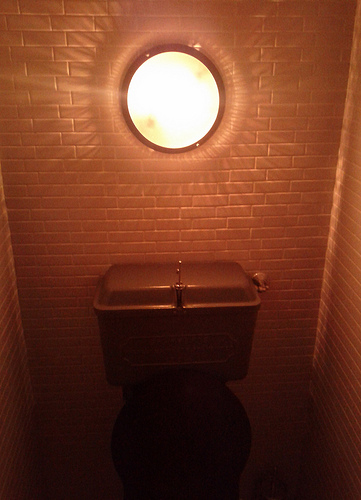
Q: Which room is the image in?
A: It is at the bathroom.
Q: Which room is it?
A: It is a bathroom.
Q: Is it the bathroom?
A: Yes, it is the bathroom.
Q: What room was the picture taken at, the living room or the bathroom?
A: It was taken at the bathroom.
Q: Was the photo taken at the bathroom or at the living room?
A: It was taken at the bathroom.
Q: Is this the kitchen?
A: No, it is the bathroom.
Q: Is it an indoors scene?
A: Yes, it is indoors.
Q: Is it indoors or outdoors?
A: It is indoors.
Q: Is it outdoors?
A: No, it is indoors.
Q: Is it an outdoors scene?
A: No, it is indoors.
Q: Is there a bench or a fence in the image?
A: No, there are no fences or benches.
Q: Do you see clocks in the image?
A: No, there are no clocks.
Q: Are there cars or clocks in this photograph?
A: No, there are no clocks or cars.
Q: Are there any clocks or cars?
A: No, there are no clocks or cars.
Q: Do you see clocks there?
A: No, there are no clocks.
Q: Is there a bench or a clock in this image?
A: No, there are no clocks or benches.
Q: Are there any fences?
A: No, there are no fences.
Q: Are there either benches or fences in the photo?
A: No, there are no fences or benches.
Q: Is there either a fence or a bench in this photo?
A: No, there are no fences or benches.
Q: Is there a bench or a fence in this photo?
A: No, there are no fences or benches.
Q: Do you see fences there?
A: No, there are no fences.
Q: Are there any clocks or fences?
A: No, there are no fences or clocks.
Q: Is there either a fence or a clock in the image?
A: No, there are no fences or clocks.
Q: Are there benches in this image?
A: No, there are no benches.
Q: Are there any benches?
A: No, there are no benches.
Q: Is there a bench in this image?
A: No, there are no benches.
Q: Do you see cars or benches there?
A: No, there are no benches or cars.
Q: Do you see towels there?
A: No, there are no towels.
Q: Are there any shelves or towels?
A: No, there are no towels or shelves.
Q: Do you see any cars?
A: No, there are no cars.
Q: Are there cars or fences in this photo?
A: No, there are no cars or fences.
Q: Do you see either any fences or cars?
A: No, there are no cars or fences.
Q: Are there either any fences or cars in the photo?
A: No, there are no cars or fences.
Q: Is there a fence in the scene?
A: No, there are no fences.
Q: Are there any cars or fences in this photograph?
A: No, there are no fences or cars.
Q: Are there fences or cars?
A: No, there are no fences or cars.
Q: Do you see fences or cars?
A: No, there are no fences or cars.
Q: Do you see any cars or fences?
A: No, there are no fences or cars.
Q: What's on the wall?
A: The bricks are on the wall.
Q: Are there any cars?
A: No, there are no cars.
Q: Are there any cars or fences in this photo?
A: No, there are no cars or fences.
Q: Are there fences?
A: No, there are no fences.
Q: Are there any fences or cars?
A: No, there are no fences or cars.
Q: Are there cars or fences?
A: No, there are no fences or cars.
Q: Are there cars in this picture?
A: No, there are no cars.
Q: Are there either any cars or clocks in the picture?
A: No, there are no cars or clocks.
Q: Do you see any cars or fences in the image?
A: No, there are no cars or fences.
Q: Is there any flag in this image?
A: No, there are no flags.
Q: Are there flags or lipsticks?
A: No, there are no flags or lipsticks.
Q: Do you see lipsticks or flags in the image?
A: No, there are no flags or lipsticks.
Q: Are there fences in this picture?
A: No, there are no fences.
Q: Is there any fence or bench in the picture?
A: No, there are no fences or benches.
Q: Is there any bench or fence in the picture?
A: No, there are no fences or benches.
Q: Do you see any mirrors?
A: No, there are no mirrors.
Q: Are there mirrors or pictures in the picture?
A: No, there are no mirrors or pictures.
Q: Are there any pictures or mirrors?
A: No, there are no mirrors or pictures.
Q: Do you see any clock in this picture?
A: No, there are no clocks.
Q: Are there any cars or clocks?
A: No, there are no clocks or cars.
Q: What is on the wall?
A: The bricks are on the wall.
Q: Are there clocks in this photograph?
A: No, there are no clocks.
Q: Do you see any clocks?
A: No, there are no clocks.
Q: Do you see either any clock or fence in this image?
A: No, there are no clocks or fences.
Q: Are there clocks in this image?
A: No, there are no clocks.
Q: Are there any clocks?
A: No, there are no clocks.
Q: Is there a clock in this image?
A: No, there are no clocks.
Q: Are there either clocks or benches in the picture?
A: No, there are no clocks or benches.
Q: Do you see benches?
A: No, there are no benches.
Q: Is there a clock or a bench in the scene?
A: No, there are no benches or clocks.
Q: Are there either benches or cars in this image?
A: No, there are no cars or benches.